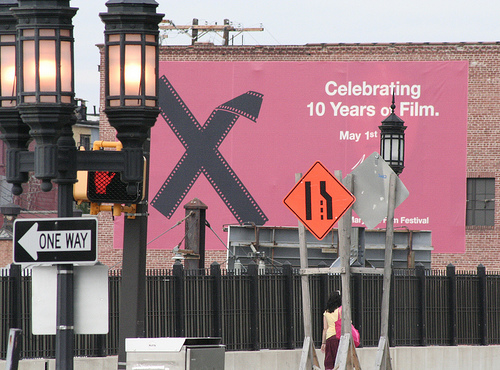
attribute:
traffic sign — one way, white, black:
[12, 218, 99, 267]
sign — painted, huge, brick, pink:
[159, 59, 469, 253]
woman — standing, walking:
[321, 289, 360, 369]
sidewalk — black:
[394, 267, 499, 369]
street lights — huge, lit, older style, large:
[0, 0, 164, 198]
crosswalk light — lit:
[76, 170, 127, 216]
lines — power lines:
[165, 19, 264, 48]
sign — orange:
[283, 159, 355, 239]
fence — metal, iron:
[394, 262, 500, 344]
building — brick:
[160, 46, 500, 270]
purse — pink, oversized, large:
[335, 307, 362, 347]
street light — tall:
[378, 87, 412, 368]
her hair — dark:
[326, 289, 347, 312]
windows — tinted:
[78, 132, 93, 150]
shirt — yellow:
[324, 308, 345, 338]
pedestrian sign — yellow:
[75, 142, 147, 217]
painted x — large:
[152, 73, 268, 228]